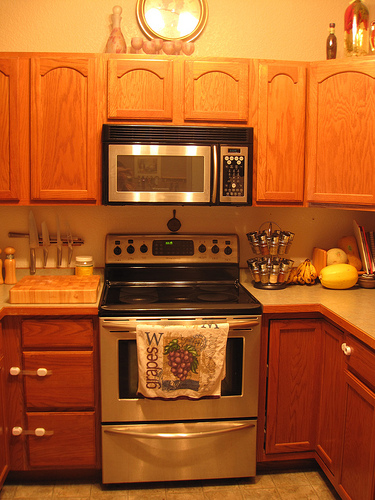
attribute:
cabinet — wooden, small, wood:
[106, 56, 178, 125]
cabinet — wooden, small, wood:
[180, 57, 254, 125]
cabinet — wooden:
[254, 59, 310, 210]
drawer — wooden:
[21, 319, 96, 350]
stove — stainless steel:
[100, 234, 264, 488]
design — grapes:
[143, 330, 204, 392]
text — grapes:
[145, 331, 164, 391]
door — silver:
[97, 317, 263, 421]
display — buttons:
[224, 154, 246, 197]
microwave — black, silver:
[100, 121, 253, 207]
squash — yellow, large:
[319, 261, 360, 289]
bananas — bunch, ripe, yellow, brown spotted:
[285, 257, 318, 285]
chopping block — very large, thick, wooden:
[7, 276, 102, 302]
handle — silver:
[211, 144, 220, 204]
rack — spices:
[246, 222, 296, 289]